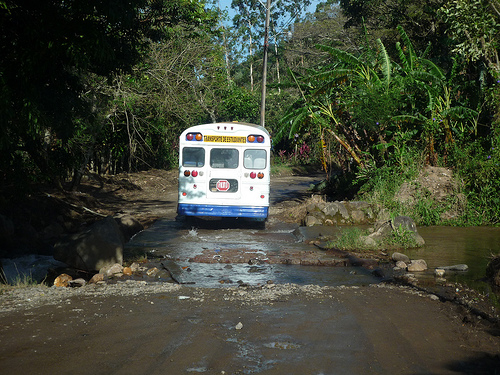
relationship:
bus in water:
[166, 117, 285, 220] [3, 184, 499, 339]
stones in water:
[4, 215, 500, 301] [3, 184, 499, 339]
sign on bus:
[213, 177, 234, 194] [166, 117, 285, 220]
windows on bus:
[183, 144, 267, 176] [166, 117, 285, 220]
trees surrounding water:
[1, 1, 499, 243] [3, 184, 499, 339]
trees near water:
[1, 1, 499, 243] [3, 184, 499, 339]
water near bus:
[3, 184, 499, 339] [166, 117, 285, 220]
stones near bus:
[4, 215, 500, 301] [166, 117, 285, 220]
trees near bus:
[1, 1, 499, 243] [166, 117, 285, 220]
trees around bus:
[1, 1, 499, 243] [166, 117, 285, 220]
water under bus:
[3, 184, 499, 339] [166, 117, 285, 220]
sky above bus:
[198, 2, 343, 68] [166, 117, 285, 220]